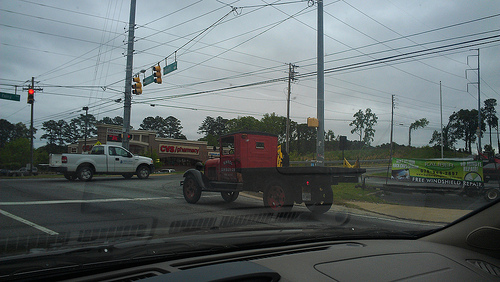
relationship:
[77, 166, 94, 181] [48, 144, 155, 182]
tire on a pickup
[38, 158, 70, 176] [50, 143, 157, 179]
tailgate on a truck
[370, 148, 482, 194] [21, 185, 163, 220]
sign next to road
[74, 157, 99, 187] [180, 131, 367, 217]
tire on a antique truck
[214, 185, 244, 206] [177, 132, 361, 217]
tire on a truck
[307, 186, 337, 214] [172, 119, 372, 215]
tire on a truck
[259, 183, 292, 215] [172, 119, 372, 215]
tire on a truck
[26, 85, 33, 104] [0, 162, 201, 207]
light at an intersection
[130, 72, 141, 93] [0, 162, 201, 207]
light at an intersection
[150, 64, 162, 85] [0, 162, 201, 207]
light at an intersection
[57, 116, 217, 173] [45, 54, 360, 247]
pharmacy at intersection